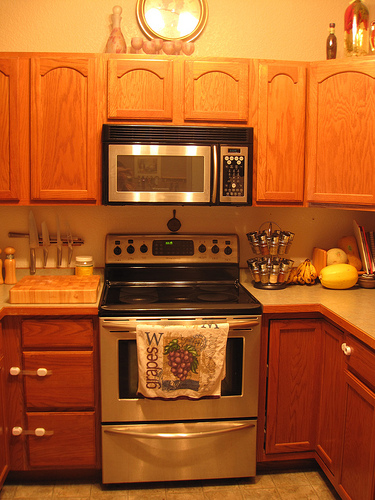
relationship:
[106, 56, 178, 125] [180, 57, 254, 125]
cabinet next to cabinet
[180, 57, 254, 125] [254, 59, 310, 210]
cabinet next to cabinet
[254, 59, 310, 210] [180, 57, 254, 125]
cabinet next to cabinet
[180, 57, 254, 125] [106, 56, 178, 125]
cabinet next to cabinet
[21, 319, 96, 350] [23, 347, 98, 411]
drawer above drawer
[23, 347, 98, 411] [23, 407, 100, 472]
drawer above drawer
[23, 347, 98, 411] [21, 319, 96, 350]
drawer below drawer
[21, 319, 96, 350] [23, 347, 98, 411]
drawer on top of drawer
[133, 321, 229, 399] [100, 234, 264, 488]
towel on stove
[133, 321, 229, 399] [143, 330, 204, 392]
towel has design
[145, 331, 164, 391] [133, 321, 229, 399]
text on towel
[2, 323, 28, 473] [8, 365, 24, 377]
door has knob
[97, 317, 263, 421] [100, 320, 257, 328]
door has handle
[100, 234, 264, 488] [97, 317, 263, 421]
stove has door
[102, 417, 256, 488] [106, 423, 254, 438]
broiler draw has handle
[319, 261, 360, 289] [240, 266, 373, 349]
squash on counter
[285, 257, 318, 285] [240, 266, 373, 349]
bananas on counter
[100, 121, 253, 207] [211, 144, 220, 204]
microwave has handle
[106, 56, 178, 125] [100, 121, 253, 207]
cabinet above microwave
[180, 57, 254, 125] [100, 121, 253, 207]
cabinet above microwave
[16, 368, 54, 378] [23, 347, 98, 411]
safety lock on drawer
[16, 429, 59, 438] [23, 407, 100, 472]
safety lock on drawer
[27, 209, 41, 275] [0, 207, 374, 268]
knife hanging on wall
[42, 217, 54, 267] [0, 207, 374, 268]
knife hanging on wall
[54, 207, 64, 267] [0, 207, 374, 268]
knife hanging on wall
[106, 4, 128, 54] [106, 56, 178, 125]
decorative bottle on cabinet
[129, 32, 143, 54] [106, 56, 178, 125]
decorative bottle on cabinet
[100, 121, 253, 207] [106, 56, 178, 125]
microwave under cabinet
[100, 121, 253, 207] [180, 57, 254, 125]
microwave under cabinet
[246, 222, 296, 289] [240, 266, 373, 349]
rack on counter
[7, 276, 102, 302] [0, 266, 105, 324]
chopping block on counter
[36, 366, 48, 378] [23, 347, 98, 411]
knob on drawer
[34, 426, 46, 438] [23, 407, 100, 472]
knob on drawer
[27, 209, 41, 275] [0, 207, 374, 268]
knife mounted on wall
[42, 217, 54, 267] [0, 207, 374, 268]
knife mounted on wall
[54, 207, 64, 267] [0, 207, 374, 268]
knife mounted on wall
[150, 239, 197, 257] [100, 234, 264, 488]
digital clock on stove